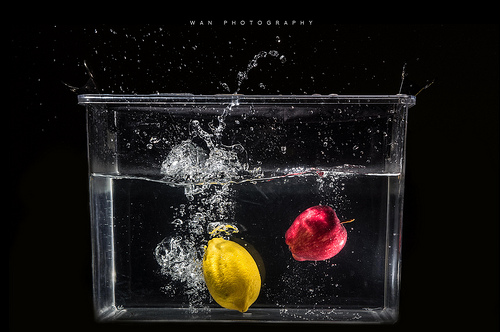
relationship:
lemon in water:
[193, 224, 272, 324] [98, 145, 401, 207]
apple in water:
[276, 194, 350, 251] [105, 177, 401, 313]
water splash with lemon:
[146, 41, 289, 180] [195, 221, 261, 321]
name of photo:
[183, 15, 313, 27] [24, 0, 442, 308]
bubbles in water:
[196, 187, 229, 217] [104, 187, 383, 313]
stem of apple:
[336, 215, 357, 227] [282, 204, 346, 259]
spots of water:
[271, 135, 287, 155] [211, 52, 280, 80]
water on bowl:
[211, 52, 280, 80] [75, 94, 413, 325]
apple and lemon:
[283, 205, 357, 261] [207, 232, 259, 313]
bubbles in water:
[151, 184, 253, 318] [96, 166, 401, 324]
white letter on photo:
[289, 17, 297, 27] [2, 0, 500, 331]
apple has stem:
[283, 205, 357, 261] [335, 213, 360, 226]